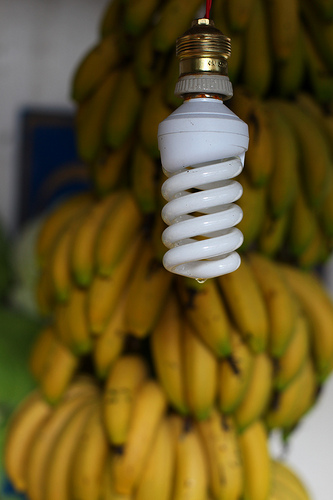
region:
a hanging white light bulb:
[151, 52, 294, 287]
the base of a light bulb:
[167, 25, 274, 100]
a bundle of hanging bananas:
[63, 278, 331, 479]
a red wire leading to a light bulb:
[182, 0, 249, 44]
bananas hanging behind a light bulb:
[54, 203, 296, 485]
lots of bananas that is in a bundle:
[51, 204, 305, 466]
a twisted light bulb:
[149, 92, 286, 297]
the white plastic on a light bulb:
[156, 90, 272, 187]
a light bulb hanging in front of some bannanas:
[155, 62, 263, 296]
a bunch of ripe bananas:
[105, 154, 300, 485]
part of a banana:
[262, 449, 270, 456]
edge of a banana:
[171, 430, 182, 445]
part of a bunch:
[138, 427, 153, 452]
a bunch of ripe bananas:
[113, 429, 128, 446]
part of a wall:
[261, 463, 275, 483]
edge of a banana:
[228, 463, 239, 471]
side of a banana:
[201, 459, 210, 467]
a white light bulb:
[152, 19, 260, 291]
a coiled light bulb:
[151, 15, 258, 306]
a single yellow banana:
[276, 260, 328, 384]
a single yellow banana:
[45, 220, 86, 312]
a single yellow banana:
[91, 197, 144, 281]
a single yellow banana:
[199, 409, 254, 498]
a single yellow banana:
[179, 420, 207, 498]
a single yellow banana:
[118, 380, 172, 497]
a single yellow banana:
[101, 363, 148, 444]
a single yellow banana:
[3, 395, 54, 492]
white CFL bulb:
[153, 93, 250, 293]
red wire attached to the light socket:
[201, 0, 214, 20]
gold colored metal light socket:
[173, 18, 232, 74]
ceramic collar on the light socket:
[170, 72, 236, 102]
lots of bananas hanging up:
[7, 2, 329, 497]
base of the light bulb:
[152, 95, 251, 166]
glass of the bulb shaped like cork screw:
[156, 149, 248, 288]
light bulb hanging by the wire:
[160, 4, 247, 293]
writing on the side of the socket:
[202, 59, 227, 70]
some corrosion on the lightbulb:
[180, 93, 227, 103]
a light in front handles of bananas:
[9, 4, 322, 498]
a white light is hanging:
[142, 6, 258, 302]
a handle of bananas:
[4, 386, 319, 498]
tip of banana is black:
[95, 417, 132, 463]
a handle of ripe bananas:
[4, 399, 311, 496]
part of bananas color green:
[236, 158, 324, 270]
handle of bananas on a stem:
[4, 2, 327, 498]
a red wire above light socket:
[186, 0, 220, 57]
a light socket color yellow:
[170, 15, 239, 114]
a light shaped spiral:
[152, 98, 252, 294]